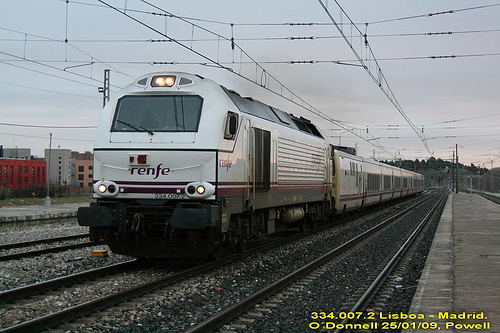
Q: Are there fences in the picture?
A: No, there are no fences.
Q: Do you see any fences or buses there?
A: No, there are no fences or buses.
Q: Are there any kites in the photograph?
A: No, there are no kites.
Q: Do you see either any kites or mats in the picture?
A: No, there are no kites or mats.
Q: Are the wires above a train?
A: Yes, the wires are above a train.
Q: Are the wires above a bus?
A: No, the wires are above a train.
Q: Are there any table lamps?
A: No, there are no table lamps.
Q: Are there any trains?
A: Yes, there is a train.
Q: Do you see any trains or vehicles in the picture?
A: Yes, there is a train.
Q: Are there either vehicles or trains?
A: Yes, there is a train.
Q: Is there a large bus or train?
A: Yes, there is a large train.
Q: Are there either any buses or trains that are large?
A: Yes, the train is large.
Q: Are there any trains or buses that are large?
A: Yes, the train is large.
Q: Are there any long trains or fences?
A: Yes, there is a long train.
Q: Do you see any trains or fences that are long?
A: Yes, the train is long.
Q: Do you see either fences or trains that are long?
A: Yes, the train is long.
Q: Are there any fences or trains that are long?
A: Yes, the train is long.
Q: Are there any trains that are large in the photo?
A: Yes, there is a large train.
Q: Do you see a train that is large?
A: Yes, there is a train that is large.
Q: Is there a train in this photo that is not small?
A: Yes, there is a large train.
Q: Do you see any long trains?
A: Yes, there is a long train.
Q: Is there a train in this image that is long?
A: Yes, there is a train that is long.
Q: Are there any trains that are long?
A: Yes, there is a train that is long.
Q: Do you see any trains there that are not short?
A: Yes, there is a long train.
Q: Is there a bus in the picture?
A: No, there are no buses.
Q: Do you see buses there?
A: No, there are no buses.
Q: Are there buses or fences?
A: No, there are no buses or fences.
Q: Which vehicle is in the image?
A: The vehicle is a train.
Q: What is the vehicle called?
A: The vehicle is a train.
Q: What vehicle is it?
A: The vehicle is a train.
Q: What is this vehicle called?
A: This is a train.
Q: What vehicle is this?
A: This is a train.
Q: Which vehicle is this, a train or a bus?
A: This is a train.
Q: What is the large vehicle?
A: The vehicle is a train.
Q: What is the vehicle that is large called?
A: The vehicle is a train.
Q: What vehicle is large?
A: The vehicle is a train.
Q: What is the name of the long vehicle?
A: The vehicle is a train.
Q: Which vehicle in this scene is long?
A: The vehicle is a train.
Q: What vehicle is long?
A: The vehicle is a train.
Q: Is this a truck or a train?
A: This is a train.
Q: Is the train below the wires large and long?
A: Yes, the train is large and long.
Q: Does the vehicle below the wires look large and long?
A: Yes, the train is large and long.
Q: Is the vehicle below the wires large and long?
A: Yes, the train is large and long.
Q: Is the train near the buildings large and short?
A: No, the train is large but long.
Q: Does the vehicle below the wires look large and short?
A: No, the train is large but long.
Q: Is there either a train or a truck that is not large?
A: No, there is a train but it is large.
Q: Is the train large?
A: Yes, the train is large.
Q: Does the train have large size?
A: Yes, the train is large.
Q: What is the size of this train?
A: The train is large.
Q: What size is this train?
A: The train is large.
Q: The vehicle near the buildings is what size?
A: The train is large.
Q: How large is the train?
A: The train is large.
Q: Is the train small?
A: No, the train is large.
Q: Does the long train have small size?
A: No, the train is large.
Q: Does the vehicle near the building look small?
A: No, the train is large.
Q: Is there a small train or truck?
A: No, there is a train but it is large.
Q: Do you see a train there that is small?
A: No, there is a train but it is large.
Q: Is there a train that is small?
A: No, there is a train but it is large.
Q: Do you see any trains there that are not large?
A: No, there is a train but it is large.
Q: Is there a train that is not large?
A: No, there is a train but it is large.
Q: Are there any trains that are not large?
A: No, there is a train but it is large.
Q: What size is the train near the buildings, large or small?
A: The train is large.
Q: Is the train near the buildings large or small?
A: The train is large.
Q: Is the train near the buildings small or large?
A: The train is large.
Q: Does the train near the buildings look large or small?
A: The train is large.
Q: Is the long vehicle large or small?
A: The train is large.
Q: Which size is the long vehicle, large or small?
A: The train is large.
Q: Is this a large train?
A: Yes, this is a large train.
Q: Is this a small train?
A: No, this is a large train.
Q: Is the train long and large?
A: Yes, the train is long and large.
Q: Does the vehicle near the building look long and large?
A: Yes, the train is long and large.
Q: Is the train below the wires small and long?
A: No, the train is long but large.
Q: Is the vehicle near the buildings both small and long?
A: No, the train is long but large.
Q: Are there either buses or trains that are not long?
A: No, there is a train but it is long.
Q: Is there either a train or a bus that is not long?
A: No, there is a train but it is long.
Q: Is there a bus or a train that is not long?
A: No, there is a train but it is long.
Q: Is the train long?
A: Yes, the train is long.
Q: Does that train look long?
A: Yes, the train is long.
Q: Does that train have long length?
A: Yes, the train is long.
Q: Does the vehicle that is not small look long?
A: Yes, the train is long.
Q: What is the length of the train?
A: The train is long.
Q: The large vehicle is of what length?
A: The train is long.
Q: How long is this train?
A: The train is long.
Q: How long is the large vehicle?
A: The train is long.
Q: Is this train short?
A: No, the train is long.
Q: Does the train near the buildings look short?
A: No, the train is long.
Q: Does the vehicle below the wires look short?
A: No, the train is long.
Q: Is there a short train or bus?
A: No, there is a train but it is long.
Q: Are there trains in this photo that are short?
A: No, there is a train but it is long.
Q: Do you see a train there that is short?
A: No, there is a train but it is long.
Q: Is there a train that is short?
A: No, there is a train but it is long.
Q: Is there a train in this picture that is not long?
A: No, there is a train but it is long.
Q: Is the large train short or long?
A: The train is long.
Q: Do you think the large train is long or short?
A: The train is long.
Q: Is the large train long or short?
A: The train is long.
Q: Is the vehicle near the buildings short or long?
A: The train is long.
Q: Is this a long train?
A: Yes, this is a long train.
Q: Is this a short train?
A: No, this is a long train.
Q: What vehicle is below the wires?
A: The vehicle is a train.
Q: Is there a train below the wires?
A: Yes, there is a train below the wires.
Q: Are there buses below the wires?
A: No, there is a train below the wires.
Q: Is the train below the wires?
A: Yes, the train is below the wires.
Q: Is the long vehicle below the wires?
A: Yes, the train is below the wires.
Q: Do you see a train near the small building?
A: Yes, there is a train near the building.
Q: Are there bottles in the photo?
A: No, there are no bottles.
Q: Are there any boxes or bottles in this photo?
A: No, there are no bottles or boxes.